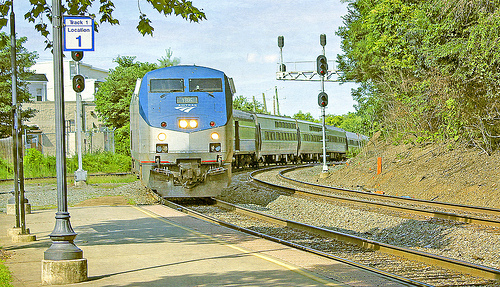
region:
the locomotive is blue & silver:
[127, 41, 252, 239]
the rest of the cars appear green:
[215, 102, 365, 163]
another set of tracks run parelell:
[288, 171, 498, 243]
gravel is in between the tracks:
[258, 186, 413, 264]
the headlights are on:
[154, 115, 222, 145]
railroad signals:
[262, 20, 364, 192]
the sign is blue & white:
[44, 10, 131, 58]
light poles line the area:
[43, 2, 95, 282]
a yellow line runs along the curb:
[139, 201, 284, 284]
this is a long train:
[88, 49, 375, 229]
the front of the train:
[134, 63, 232, 201]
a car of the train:
[228, 108, 257, 169]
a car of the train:
[253, 110, 301, 163]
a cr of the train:
[296, 113, 347, 165]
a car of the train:
[345, 127, 368, 161]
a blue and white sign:
[59, 15, 88, 51]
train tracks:
[176, 188, 499, 285]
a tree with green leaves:
[98, 58, 142, 175]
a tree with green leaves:
[1, 33, 41, 150]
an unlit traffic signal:
[309, 49, 333, 115]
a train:
[123, 62, 282, 278]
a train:
[99, 12, 278, 199]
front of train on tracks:
[128, 59, 243, 211]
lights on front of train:
[175, 116, 200, 129]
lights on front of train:
[211, 131, 221, 143]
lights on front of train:
[155, 129, 167, 143]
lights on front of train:
[155, 119, 168, 132]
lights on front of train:
[210, 115, 219, 125]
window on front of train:
[188, 72, 226, 94]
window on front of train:
[149, 73, 185, 91]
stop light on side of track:
[272, 25, 350, 178]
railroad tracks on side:
[322, 155, 439, 281]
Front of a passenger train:
[120, 60, 240, 210]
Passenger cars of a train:
[236, 100, 311, 165]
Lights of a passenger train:
[170, 110, 205, 136]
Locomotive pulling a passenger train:
[120, 55, 240, 202]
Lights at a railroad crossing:
[308, 30, 334, 186]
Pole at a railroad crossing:
[32, 100, 88, 285]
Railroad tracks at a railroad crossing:
[246, 202, 347, 274]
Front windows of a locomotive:
[140, 71, 225, 96]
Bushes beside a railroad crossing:
[382, 0, 490, 226]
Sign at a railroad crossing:
[59, 10, 97, 57]